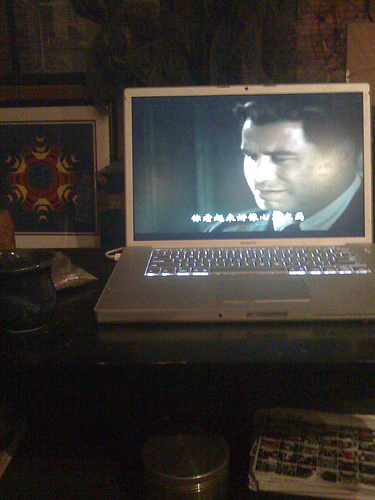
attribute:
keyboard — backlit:
[142, 247, 362, 276]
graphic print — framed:
[0, 74, 122, 261]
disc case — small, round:
[137, 424, 237, 498]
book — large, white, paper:
[246, 399, 363, 497]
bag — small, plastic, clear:
[45, 250, 102, 290]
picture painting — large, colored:
[2, 1, 138, 93]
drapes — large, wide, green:
[98, 3, 301, 116]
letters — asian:
[189, 209, 304, 222]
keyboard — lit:
[146, 246, 371, 275]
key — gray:
[146, 265, 163, 274]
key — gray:
[208, 265, 287, 276]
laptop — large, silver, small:
[93, 81, 373, 335]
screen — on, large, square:
[130, 94, 364, 239]